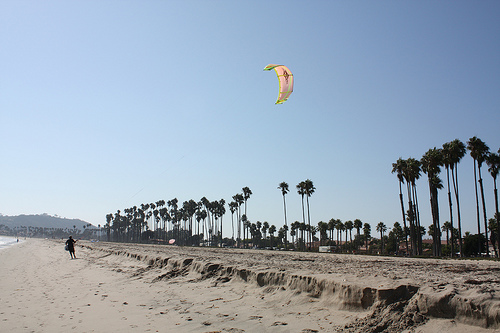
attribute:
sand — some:
[31, 233, 398, 331]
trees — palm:
[92, 136, 480, 248]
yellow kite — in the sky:
[260, 52, 301, 110]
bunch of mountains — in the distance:
[6, 204, 98, 242]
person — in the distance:
[53, 230, 94, 269]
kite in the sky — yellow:
[254, 58, 306, 109]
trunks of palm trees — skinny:
[389, 153, 431, 264]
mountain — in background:
[7, 204, 103, 253]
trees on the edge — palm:
[96, 207, 172, 255]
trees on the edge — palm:
[187, 178, 331, 248]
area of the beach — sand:
[77, 252, 185, 332]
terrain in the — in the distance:
[9, 204, 93, 246]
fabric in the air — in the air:
[256, 51, 317, 120]